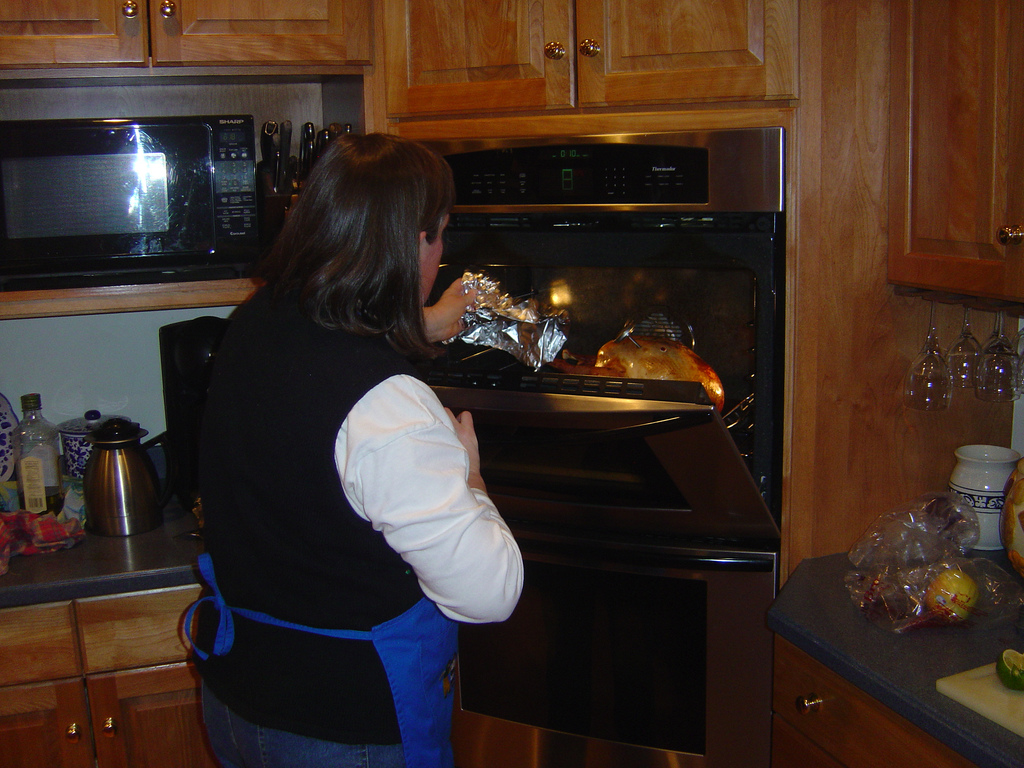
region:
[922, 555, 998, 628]
Apple inside of plastic bag.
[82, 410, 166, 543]
Tea canister on top of the counter.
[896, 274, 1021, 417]
Three wine glasses under the cabinet.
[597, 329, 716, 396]
Large chicken inside of the oven.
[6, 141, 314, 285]
Buttons on the front of the motorcycle.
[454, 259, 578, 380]
Piece of foil in the woman's hand.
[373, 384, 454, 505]
White sleeve on the woman's arm.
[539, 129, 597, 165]
Digital display on the oven.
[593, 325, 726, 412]
turkey cooking in an oven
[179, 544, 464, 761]
an apron a women is wearing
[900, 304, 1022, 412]
wine glases hanging from cupboard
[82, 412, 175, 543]
teapot on a counter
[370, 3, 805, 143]
cupboards in a kitchen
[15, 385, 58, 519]
olive oil on a counter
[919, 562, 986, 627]
an orange in a plastic bag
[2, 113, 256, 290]
Black microwave on shelf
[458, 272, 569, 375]
Crushed up foil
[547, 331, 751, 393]
Chicken baking in the oven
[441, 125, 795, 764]
Double oven in the kitchen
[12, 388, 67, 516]
Cooking oil on the counter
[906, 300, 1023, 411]
Wine glasses hanging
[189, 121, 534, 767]
Lady cooking in the kitchen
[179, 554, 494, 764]
Blue apron on the woman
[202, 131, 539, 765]
Woman cooking dinner.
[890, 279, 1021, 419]
Wine glasses hang in the kitchen.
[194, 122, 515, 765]
Woman wearing a blue apron.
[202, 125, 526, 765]
Woman with brown hair.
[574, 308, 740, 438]
Poultry cooking in the oven.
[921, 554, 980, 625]
Fruit on kitchen counter.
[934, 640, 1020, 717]
Sliced lime on cutting board.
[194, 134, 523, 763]
Woman placing food in oven.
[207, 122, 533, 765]
Woman opening oven door.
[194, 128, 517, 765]
Woman cooking in kitchen.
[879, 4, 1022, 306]
a wooden cabinet with round handle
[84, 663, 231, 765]
a wooden cabinet with round handle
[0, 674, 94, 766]
a wooden cabinet with round handle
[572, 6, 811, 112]
a wooden cabinet with round handle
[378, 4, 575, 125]
a wooden cabinet with round handle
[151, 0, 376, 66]
a wooden cabinet with round handle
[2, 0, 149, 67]
a wooden cabinet with round handle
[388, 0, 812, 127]
a wooden cabinet with round handle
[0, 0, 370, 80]
a wooden cabinet with round handle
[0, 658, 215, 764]
a wooden cabinet with round handle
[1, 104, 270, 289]
a black microwave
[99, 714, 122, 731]
a gold cabinet knob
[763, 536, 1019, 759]
a gray kitchen counter top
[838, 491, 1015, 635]
a clear plastic bag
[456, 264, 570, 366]
gray aluminum foil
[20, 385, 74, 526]
a small bottle of oil